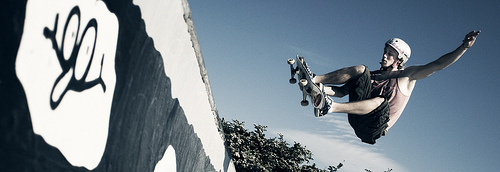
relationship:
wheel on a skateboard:
[296, 78, 310, 87] [286, 54, 324, 109]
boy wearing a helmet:
[286, 30, 481, 146] [386, 36, 411, 61]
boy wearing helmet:
[286, 30, 481, 146] [387, 32, 412, 67]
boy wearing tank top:
[286, 30, 481, 146] [369, 66, 412, 133]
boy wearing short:
[286, 30, 481, 146] [338, 78, 388, 138]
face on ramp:
[373, 32, 415, 82] [0, 0, 237, 170]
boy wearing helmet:
[286, 29, 480, 143] [379, 36, 412, 68]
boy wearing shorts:
[286, 29, 480, 143] [345, 66, 388, 144]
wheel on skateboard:
[300, 100, 309, 106] [286, 51, 327, 111]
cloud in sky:
[258, 124, 407, 169] [198, 7, 494, 170]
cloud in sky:
[321, 110, 365, 145] [198, 7, 494, 170]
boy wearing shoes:
[286, 30, 481, 146] [272, 33, 357, 111]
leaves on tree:
[244, 141, 282, 162] [213, 105, 358, 170]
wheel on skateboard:
[286, 56, 300, 68] [281, 49, 329, 122]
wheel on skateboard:
[286, 72, 298, 87] [281, 49, 329, 122]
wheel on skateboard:
[297, 74, 310, 88] [281, 49, 329, 122]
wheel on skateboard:
[297, 97, 309, 109] [281, 49, 329, 122]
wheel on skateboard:
[296, 78, 310, 87] [283, 53, 332, 120]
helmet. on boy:
[377, 29, 417, 69] [286, 30, 481, 146]